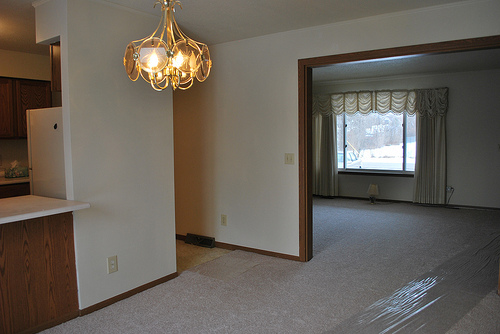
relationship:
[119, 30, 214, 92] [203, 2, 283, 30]
chandelier on roof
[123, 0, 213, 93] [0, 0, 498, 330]
chandelier in dining area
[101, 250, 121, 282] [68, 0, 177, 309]
outlet in wall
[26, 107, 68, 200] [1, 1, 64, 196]
fridge in kitchen area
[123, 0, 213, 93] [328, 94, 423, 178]
chandelier sitting beneath window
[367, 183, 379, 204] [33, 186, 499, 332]
lamp on carpet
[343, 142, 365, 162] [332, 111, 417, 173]
shrubs seen through window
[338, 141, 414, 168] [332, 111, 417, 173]
grass seen through window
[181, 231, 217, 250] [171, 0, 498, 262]
object resting against wall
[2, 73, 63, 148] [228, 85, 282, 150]
cabinets against wall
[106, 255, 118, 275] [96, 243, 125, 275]
outlet on wall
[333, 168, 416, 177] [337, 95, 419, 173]
shelf below window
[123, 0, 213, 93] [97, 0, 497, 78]
chandelier hanging from ceiling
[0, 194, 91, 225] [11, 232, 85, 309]
counter over wood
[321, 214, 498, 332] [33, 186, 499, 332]
cover on carpet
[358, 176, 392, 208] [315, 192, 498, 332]
lamp sitting on floor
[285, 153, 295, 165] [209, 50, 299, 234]
light switch on wall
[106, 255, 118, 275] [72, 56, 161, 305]
outlet in wall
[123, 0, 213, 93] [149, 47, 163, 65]
chandelier with light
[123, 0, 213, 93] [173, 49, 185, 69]
chandelier with light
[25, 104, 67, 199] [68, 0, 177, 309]
fridge behind wall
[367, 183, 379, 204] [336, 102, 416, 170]
lamp under window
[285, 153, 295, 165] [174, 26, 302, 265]
light switch in wall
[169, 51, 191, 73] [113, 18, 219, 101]
light bulbs in chandelier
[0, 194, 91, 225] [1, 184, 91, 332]
counter for bar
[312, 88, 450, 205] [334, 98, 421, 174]
curtain on window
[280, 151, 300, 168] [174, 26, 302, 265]
light switch on wall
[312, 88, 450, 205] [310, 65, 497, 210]
curtain against wall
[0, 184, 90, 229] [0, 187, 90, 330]
counter supported by frame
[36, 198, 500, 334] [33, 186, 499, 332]
carpet on carpet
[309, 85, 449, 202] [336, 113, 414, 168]
curtain on window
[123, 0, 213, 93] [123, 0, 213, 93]
chandelier with chandelier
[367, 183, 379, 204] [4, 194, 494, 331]
lamp on floor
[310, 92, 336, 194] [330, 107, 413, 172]
curtain on side of window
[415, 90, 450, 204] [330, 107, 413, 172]
curtain on side of window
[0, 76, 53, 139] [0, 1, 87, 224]
cabinets in kitchen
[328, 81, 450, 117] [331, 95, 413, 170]
valance hanging over window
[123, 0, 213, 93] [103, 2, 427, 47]
chandelier hanging in roof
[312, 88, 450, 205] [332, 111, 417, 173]
curtain in window